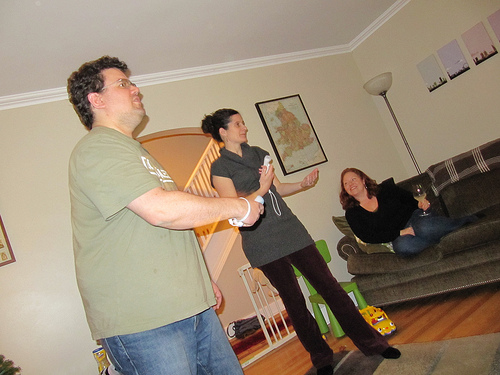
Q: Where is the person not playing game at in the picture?
A: Right side couch.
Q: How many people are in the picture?
A: Three.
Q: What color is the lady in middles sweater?
A: Gray.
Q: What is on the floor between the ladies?
A: Child's toy.